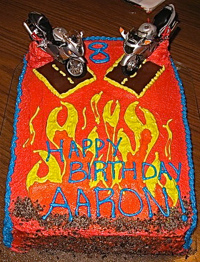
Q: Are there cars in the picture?
A: No, there are no cars.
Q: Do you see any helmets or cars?
A: No, there are no cars or helmets.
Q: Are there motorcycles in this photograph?
A: Yes, there is a motorcycle.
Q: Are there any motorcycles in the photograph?
A: Yes, there is a motorcycle.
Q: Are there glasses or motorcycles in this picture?
A: Yes, there is a motorcycle.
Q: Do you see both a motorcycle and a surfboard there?
A: No, there is a motorcycle but no surfboards.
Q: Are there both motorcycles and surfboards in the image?
A: No, there is a motorcycle but no surfboards.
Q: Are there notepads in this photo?
A: No, there are no notepads.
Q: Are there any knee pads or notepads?
A: No, there are no notepads or knee pads.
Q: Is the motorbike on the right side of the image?
A: Yes, the motorbike is on the right of the image.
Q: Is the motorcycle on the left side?
A: No, the motorcycle is on the right of the image.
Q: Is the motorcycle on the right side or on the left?
A: The motorcycle is on the right of the image.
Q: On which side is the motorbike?
A: The motorbike is on the right of the image.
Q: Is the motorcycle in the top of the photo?
A: Yes, the motorcycle is in the top of the image.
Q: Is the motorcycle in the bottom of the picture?
A: No, the motorcycle is in the top of the image.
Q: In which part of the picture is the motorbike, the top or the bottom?
A: The motorbike is in the top of the image.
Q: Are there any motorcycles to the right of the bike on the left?
A: Yes, there is a motorcycle to the right of the bike.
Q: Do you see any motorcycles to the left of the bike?
A: No, the motorcycle is to the right of the bike.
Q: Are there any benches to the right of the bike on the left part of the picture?
A: No, there is a motorcycle to the right of the bike.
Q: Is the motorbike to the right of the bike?
A: Yes, the motorbike is to the right of the bike.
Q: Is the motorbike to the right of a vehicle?
A: No, the motorbike is to the right of the bike.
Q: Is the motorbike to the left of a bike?
A: No, the motorbike is to the right of a bike.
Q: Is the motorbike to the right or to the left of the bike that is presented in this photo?
A: The motorbike is to the right of the bike.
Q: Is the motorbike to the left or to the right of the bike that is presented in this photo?
A: The motorbike is to the right of the bike.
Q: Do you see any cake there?
A: Yes, there is a cake.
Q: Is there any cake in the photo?
A: Yes, there is a cake.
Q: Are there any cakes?
A: Yes, there is a cake.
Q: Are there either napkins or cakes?
A: Yes, there is a cake.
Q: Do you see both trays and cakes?
A: No, there is a cake but no trays.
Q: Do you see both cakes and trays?
A: No, there is a cake but no trays.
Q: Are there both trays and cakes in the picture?
A: No, there is a cake but no trays.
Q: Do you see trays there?
A: No, there are no trays.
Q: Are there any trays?
A: No, there are no trays.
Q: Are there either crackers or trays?
A: No, there are no trays or crackers.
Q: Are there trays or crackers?
A: No, there are no trays or crackers.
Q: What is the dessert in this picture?
A: The dessert is a cake.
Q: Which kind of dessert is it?
A: The dessert is a cake.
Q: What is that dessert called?
A: That is a cake.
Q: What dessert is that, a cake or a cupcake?
A: That is a cake.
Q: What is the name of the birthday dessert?
A: The dessert is a cake.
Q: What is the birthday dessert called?
A: The dessert is a cake.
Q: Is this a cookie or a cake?
A: This is a cake.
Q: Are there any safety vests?
A: No, there are no safety vests.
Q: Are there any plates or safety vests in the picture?
A: No, there are no safety vests or plates.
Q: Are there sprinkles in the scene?
A: Yes, there are sprinkles.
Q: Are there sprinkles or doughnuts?
A: Yes, there are sprinkles.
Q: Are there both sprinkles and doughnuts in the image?
A: No, there are sprinkles but no donuts.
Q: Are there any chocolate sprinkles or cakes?
A: Yes, there are chocolate sprinkles.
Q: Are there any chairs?
A: No, there are no chairs.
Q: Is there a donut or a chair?
A: No, there are no chairs or donuts.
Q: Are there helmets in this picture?
A: No, there are no helmets.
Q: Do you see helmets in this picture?
A: No, there are no helmets.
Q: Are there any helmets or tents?
A: No, there are no helmets or tents.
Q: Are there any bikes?
A: Yes, there is a bike.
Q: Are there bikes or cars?
A: Yes, there is a bike.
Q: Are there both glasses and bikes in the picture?
A: No, there is a bike but no glasses.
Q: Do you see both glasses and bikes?
A: No, there is a bike but no glasses.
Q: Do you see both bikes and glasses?
A: No, there is a bike but no glasses.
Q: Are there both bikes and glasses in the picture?
A: No, there is a bike but no glasses.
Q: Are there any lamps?
A: No, there are no lamps.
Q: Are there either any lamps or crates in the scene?
A: No, there are no lamps or crates.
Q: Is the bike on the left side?
A: Yes, the bike is on the left of the image.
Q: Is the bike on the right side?
A: No, the bike is on the left of the image.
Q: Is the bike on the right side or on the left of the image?
A: The bike is on the left of the image.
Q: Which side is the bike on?
A: The bike is on the left of the image.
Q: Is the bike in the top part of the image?
A: Yes, the bike is in the top of the image.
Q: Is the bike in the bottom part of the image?
A: No, the bike is in the top of the image.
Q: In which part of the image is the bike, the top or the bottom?
A: The bike is in the top of the image.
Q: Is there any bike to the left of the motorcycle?
A: Yes, there is a bike to the left of the motorcycle.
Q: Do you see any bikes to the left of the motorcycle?
A: Yes, there is a bike to the left of the motorcycle.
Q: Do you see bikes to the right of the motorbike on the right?
A: No, the bike is to the left of the motorbike.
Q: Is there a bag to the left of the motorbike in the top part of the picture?
A: No, there is a bike to the left of the motorbike.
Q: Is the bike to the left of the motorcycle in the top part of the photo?
A: Yes, the bike is to the left of the motorbike.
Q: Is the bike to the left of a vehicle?
A: No, the bike is to the left of the motorbike.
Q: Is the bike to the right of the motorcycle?
A: No, the bike is to the left of the motorcycle.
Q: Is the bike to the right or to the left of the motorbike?
A: The bike is to the left of the motorbike.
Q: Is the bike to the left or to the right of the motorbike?
A: The bike is to the left of the motorbike.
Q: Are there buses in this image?
A: No, there are no buses.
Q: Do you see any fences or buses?
A: No, there are no buses or fences.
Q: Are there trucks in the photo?
A: No, there are no trucks.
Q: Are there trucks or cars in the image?
A: No, there are no trucks or cars.